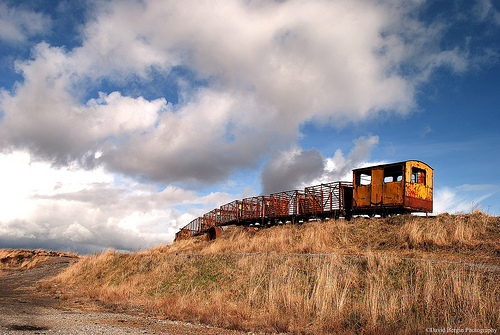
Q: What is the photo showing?
A: It is showing a field.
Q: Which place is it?
A: It is a field.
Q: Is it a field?
A: Yes, it is a field.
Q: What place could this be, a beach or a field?
A: It is a field.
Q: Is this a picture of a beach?
A: No, the picture is showing a field.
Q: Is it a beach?
A: No, it is a field.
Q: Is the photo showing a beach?
A: No, the picture is showing a field.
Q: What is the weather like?
A: It is cloudy.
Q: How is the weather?
A: It is cloudy.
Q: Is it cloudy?
A: Yes, it is cloudy.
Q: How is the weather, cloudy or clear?
A: It is cloudy.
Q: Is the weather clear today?
A: No, it is cloudy.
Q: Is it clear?
A: No, it is cloudy.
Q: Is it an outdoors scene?
A: Yes, it is outdoors.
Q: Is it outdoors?
A: Yes, it is outdoors.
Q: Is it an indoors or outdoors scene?
A: It is outdoors.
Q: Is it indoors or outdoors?
A: It is outdoors.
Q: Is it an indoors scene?
A: No, it is outdoors.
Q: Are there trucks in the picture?
A: No, there are no trucks.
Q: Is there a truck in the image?
A: No, there are no trucks.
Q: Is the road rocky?
A: Yes, the road is rocky.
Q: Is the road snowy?
A: No, the road is rocky.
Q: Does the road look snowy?
A: No, the road is rocky.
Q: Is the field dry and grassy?
A: Yes, the field is dry and grassy.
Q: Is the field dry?
A: Yes, the field is dry.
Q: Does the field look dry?
A: Yes, the field is dry.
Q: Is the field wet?
A: No, the field is dry.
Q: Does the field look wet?
A: No, the field is dry.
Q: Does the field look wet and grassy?
A: No, the field is grassy but dry.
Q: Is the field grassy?
A: Yes, the field is grassy.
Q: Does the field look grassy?
A: Yes, the field is grassy.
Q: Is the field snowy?
A: No, the field is grassy.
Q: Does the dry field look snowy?
A: No, the field is grassy.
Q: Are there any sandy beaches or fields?
A: No, there is a field but it is grassy.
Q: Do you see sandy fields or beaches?
A: No, there is a field but it is grassy.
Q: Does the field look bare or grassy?
A: The field is grassy.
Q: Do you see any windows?
A: Yes, there is a window.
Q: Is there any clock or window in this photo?
A: Yes, there is a window.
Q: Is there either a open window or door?
A: Yes, there is an open window.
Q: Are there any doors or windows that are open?
A: Yes, the window is open.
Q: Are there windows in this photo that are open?
A: Yes, there is an open window.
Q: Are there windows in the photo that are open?
A: Yes, there is a window that is open.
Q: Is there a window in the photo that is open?
A: Yes, there is a window that is open.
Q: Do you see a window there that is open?
A: Yes, there is a window that is open.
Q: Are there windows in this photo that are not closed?
A: Yes, there is a open window.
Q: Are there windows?
A: Yes, there is a window.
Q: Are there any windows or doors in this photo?
A: Yes, there is a window.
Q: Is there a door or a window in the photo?
A: Yes, there is a window.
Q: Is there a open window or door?
A: Yes, there is an open window.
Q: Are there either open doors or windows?
A: Yes, there is an open window.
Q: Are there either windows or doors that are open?
A: Yes, the window is open.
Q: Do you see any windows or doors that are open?
A: Yes, the window is open.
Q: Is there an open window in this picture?
A: Yes, there is an open window.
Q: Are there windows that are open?
A: Yes, there is a window that is open.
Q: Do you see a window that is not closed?
A: Yes, there is a open window.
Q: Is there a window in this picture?
A: Yes, there is a window.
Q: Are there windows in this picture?
A: Yes, there is a window.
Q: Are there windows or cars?
A: Yes, there is a window.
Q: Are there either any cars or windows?
A: Yes, there is a window.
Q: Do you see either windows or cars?
A: Yes, there is a window.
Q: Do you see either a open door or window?
A: Yes, there is an open window.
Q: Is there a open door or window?
A: Yes, there is an open window.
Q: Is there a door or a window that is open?
A: Yes, the window is open.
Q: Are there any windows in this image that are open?
A: Yes, there is a window that is open.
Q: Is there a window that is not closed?
A: Yes, there is a open window.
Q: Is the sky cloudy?
A: Yes, the sky is cloudy.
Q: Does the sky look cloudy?
A: Yes, the sky is cloudy.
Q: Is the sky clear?
A: No, the sky is cloudy.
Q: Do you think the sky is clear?
A: No, the sky is cloudy.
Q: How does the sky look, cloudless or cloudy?
A: The sky is cloudy.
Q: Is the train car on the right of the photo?
A: Yes, the train car is on the right of the image.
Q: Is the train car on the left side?
A: No, the train car is on the right of the image.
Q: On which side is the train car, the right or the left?
A: The train car is on the right of the image.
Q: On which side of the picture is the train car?
A: The train car is on the right of the image.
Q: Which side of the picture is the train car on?
A: The train car is on the right of the image.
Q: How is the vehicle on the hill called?
A: The vehicle is a train car.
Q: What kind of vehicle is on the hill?
A: The vehicle is a train car.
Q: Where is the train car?
A: The train car is on the hill.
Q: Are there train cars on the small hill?
A: Yes, there is a train car on the hill.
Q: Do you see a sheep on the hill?
A: No, there is a train car on the hill.